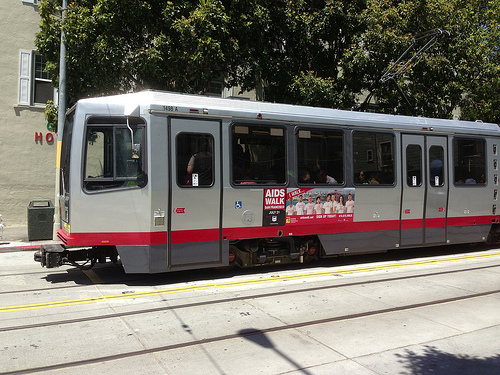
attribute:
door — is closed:
[388, 126, 465, 256]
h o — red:
[33, 129, 56, 151]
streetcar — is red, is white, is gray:
[37, 86, 497, 271]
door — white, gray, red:
[167, 115, 223, 267]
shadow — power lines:
[245, 325, 312, 371]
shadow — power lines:
[398, 340, 498, 372]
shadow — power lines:
[2, 250, 495, 372]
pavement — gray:
[0, 245, 495, 372]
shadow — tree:
[392, 342, 499, 373]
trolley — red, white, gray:
[26, 78, 499, 273]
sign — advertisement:
[262, 187, 358, 228]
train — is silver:
[52, 57, 494, 266]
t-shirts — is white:
[285, 201, 298, 212]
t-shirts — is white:
[295, 198, 306, 218]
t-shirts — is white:
[303, 201, 316, 218]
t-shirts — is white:
[315, 202, 324, 216]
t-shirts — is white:
[343, 200, 357, 214]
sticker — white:
[189, 171, 199, 185]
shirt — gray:
[185, 151, 199, 164]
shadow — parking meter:
[233, 324, 311, 374]